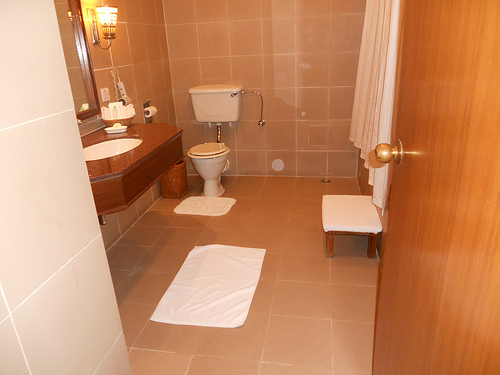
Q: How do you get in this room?
A: Open door.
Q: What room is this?
A: Bathroom.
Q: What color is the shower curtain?
A: White.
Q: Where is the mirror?
A: Above the sink.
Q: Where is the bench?
A: In front of tub.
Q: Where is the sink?
A: On the left.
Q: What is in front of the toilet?
A: Floormat.